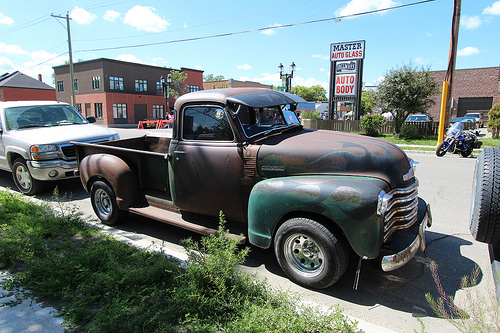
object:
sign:
[335, 60, 358, 75]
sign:
[137, 119, 174, 130]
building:
[385, 65, 500, 137]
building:
[51, 57, 205, 128]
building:
[0, 69, 58, 103]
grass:
[0, 186, 374, 333]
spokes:
[283, 232, 325, 278]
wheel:
[270, 215, 353, 290]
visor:
[225, 89, 297, 109]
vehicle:
[0, 99, 121, 196]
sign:
[331, 40, 365, 61]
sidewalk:
[342, 131, 498, 156]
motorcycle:
[436, 120, 484, 159]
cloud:
[330, 0, 402, 20]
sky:
[0, 0, 500, 98]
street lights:
[276, 61, 285, 73]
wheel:
[90, 179, 130, 226]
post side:
[436, 80, 451, 147]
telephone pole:
[65, 10, 79, 109]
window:
[180, 105, 236, 143]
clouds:
[101, 9, 124, 24]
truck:
[469, 133, 500, 303]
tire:
[467, 145, 500, 244]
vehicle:
[69, 86, 435, 292]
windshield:
[233, 101, 301, 139]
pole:
[278, 61, 297, 94]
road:
[0, 125, 500, 333]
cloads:
[120, 3, 172, 36]